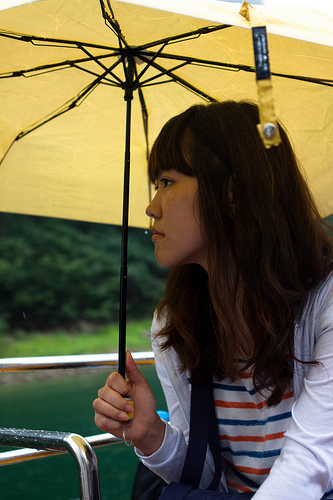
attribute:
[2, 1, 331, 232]
umbrella — yellow, tan, black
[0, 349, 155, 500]
railing — metal, silver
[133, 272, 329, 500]
shirt — striped, white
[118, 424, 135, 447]
ring — metal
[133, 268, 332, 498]
jacket — white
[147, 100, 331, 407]
hair — dark, brown, shoulder length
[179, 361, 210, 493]
strap — black, blue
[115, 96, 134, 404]
pole — metal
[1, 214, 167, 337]
bush — green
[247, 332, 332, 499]
sleeve — white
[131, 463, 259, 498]
bag — blue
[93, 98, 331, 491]
girl — seated, young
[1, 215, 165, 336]
trees — green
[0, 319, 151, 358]
grass — green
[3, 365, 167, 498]
water — calm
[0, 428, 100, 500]
rail — wet